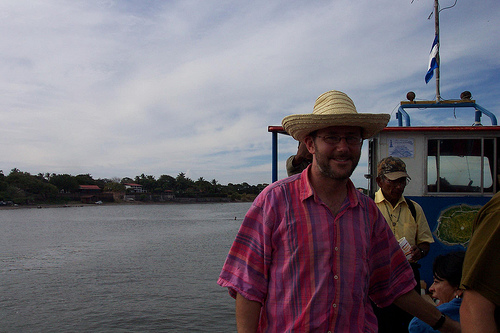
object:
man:
[217, 89, 461, 333]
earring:
[453, 293, 459, 299]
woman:
[406, 248, 464, 332]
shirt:
[368, 187, 435, 262]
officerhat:
[281, 89, 391, 140]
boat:
[267, 0, 499, 306]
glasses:
[314, 135, 363, 145]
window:
[439, 138, 495, 191]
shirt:
[217, 162, 421, 332]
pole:
[434, 0, 440, 99]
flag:
[423, 32, 440, 84]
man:
[368, 155, 438, 332]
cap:
[377, 155, 409, 180]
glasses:
[383, 178, 410, 185]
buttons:
[332, 303, 336, 307]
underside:
[295, 120, 379, 130]